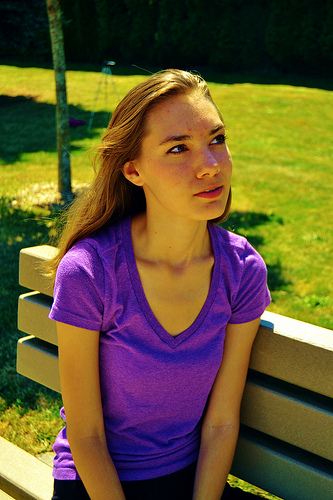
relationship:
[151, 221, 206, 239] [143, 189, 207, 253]
line in woman's neck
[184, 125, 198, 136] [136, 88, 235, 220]
acne on girl's face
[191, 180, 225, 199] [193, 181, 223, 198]
red lipstick on red lipstick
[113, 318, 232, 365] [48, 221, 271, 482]
break in purple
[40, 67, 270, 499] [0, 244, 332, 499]
girl sitting on bench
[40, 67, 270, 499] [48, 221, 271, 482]
girl wearing purple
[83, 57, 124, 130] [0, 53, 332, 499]
tripod standing on grass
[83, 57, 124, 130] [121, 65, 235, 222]
tripod behind girl's head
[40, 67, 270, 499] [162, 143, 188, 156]
girl has eye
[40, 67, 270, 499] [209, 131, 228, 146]
girl has eye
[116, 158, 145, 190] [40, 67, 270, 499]
right ear of girl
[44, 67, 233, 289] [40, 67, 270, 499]
hair of girl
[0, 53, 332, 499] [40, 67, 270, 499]
grass behind girl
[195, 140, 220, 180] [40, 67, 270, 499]
nose of girl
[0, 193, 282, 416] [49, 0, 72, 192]
shadow of tree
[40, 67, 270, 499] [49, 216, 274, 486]
girl in purple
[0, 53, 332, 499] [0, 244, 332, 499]
grass behind bench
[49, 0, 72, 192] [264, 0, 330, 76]
trunk of tree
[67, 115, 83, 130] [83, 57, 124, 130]
purple thing next to tripod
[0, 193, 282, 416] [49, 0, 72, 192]
shadow from tree